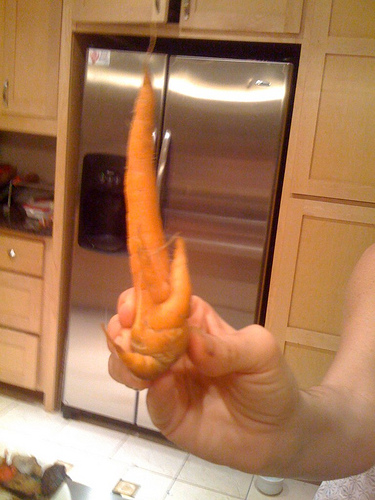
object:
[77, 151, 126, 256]
dispenser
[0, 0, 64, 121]
cabinets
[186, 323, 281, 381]
thumb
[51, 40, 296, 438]
toilet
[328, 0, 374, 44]
wooden cabinet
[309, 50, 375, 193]
wooden cabinet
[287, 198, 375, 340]
wooden cabinet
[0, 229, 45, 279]
kitchen drawer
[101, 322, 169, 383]
pinky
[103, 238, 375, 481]
person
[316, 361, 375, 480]
elbow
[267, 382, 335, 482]
wrist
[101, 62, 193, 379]
carrots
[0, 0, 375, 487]
wall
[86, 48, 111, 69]
tag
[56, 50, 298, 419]
refrigerator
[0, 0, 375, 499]
kitchen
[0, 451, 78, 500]
grout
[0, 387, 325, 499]
floor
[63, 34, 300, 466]
fridge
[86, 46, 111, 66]
magnet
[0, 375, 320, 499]
tile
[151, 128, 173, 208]
handles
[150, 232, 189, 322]
bifurcations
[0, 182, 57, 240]
counter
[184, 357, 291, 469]
palm